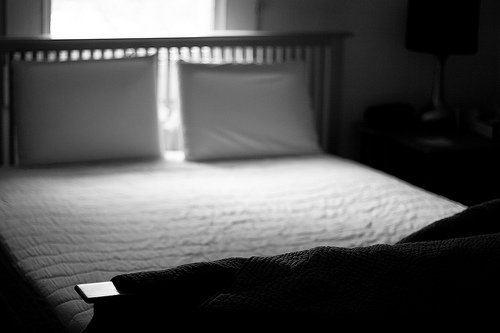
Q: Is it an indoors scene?
A: Yes, it is indoors.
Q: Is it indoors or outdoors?
A: It is indoors.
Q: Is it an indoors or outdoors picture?
A: It is indoors.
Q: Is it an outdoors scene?
A: No, it is indoors.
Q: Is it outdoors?
A: No, it is indoors.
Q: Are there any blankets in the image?
A: Yes, there is a blanket.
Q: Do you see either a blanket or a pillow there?
A: Yes, there is a blanket.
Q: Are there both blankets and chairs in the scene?
A: No, there is a blanket but no chairs.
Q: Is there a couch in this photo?
A: No, there are no couches.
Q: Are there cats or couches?
A: No, there are no couches or cats.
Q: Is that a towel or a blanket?
A: That is a blanket.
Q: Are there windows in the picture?
A: Yes, there is a window.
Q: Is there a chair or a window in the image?
A: Yes, there is a window.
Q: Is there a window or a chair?
A: Yes, there is a window.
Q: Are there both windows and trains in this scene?
A: No, there is a window but no trains.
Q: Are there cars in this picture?
A: No, there are no cars.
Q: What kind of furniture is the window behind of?
A: The window is behind the bed.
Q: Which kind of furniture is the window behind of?
A: The window is behind the bed.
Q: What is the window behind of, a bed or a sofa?
A: The window is behind a bed.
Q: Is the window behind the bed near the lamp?
A: Yes, the window is behind the bed.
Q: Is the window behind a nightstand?
A: No, the window is behind the bed.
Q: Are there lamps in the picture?
A: Yes, there is a lamp.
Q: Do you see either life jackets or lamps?
A: Yes, there is a lamp.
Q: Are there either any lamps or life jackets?
A: Yes, there is a lamp.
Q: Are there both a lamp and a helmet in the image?
A: No, there is a lamp but no helmets.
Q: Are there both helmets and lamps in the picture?
A: No, there is a lamp but no helmets.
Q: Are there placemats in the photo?
A: No, there are no placemats.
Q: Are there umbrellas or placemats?
A: No, there are no placemats or umbrellas.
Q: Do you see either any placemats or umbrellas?
A: No, there are no placemats or umbrellas.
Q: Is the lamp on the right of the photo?
A: Yes, the lamp is on the right of the image.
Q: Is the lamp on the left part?
A: No, the lamp is on the right of the image.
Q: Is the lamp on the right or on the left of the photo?
A: The lamp is on the right of the image.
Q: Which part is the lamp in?
A: The lamp is on the right of the image.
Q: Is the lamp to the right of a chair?
A: No, the lamp is to the right of the pillow.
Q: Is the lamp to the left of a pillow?
A: No, the lamp is to the right of a pillow.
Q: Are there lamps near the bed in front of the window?
A: Yes, there is a lamp near the bed.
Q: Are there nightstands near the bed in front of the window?
A: No, there is a lamp near the bed.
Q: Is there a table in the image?
A: Yes, there is a table.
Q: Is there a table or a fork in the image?
A: Yes, there is a table.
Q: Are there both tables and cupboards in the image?
A: No, there is a table but no cupboards.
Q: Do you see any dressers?
A: No, there are no dressers.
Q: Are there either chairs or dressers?
A: No, there are no dressers or chairs.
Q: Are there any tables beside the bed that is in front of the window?
A: Yes, there is a table beside the bed.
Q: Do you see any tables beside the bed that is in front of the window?
A: Yes, there is a table beside the bed.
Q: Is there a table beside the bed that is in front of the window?
A: Yes, there is a table beside the bed.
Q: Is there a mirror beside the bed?
A: No, there is a table beside the bed.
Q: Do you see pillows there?
A: Yes, there is a pillow.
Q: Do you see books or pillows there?
A: Yes, there is a pillow.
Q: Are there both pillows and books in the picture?
A: No, there is a pillow but no books.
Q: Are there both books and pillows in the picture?
A: No, there is a pillow but no books.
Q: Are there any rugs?
A: No, there are no rugs.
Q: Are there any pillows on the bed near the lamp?
A: Yes, there is a pillow on the bed.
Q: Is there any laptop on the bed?
A: No, there is a pillow on the bed.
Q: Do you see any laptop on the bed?
A: No, there is a pillow on the bed.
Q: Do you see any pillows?
A: Yes, there is a pillow.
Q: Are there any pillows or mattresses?
A: Yes, there is a pillow.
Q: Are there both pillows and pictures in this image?
A: No, there is a pillow but no pictures.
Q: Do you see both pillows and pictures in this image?
A: No, there is a pillow but no pictures.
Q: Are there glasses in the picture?
A: No, there are no glasses.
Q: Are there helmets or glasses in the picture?
A: No, there are no glasses or helmets.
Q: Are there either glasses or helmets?
A: No, there are no glasses or helmets.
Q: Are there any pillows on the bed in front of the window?
A: Yes, there is a pillow on the bed.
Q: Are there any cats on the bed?
A: No, there is a pillow on the bed.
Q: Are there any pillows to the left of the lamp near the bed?
A: Yes, there is a pillow to the left of the lamp.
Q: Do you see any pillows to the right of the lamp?
A: No, the pillow is to the left of the lamp.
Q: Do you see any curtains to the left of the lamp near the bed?
A: No, there is a pillow to the left of the lamp.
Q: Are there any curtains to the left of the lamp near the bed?
A: No, there is a pillow to the left of the lamp.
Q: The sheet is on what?
A: The sheet is on the bed.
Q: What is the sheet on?
A: The sheet is on the bed.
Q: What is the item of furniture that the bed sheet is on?
A: The piece of furniture is a bed.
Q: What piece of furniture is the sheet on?
A: The bed sheet is on the bed.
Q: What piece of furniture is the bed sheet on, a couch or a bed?
A: The bed sheet is on a bed.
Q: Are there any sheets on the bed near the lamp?
A: Yes, there is a sheet on the bed.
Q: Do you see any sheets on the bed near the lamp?
A: Yes, there is a sheet on the bed.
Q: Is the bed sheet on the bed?
A: Yes, the bed sheet is on the bed.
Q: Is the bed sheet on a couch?
A: No, the bed sheet is on the bed.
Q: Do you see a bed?
A: Yes, there is a bed.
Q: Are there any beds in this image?
A: Yes, there is a bed.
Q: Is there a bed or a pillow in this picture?
A: Yes, there is a bed.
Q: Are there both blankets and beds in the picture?
A: Yes, there are both a bed and a blanket.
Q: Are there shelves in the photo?
A: No, there are no shelves.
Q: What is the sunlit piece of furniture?
A: The piece of furniture is a bed.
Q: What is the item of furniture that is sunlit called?
A: The piece of furniture is a bed.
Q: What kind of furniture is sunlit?
A: The furniture is a bed.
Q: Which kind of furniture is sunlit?
A: The furniture is a bed.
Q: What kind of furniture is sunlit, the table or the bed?
A: The bed is sunlit.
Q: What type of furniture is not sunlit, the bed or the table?
A: The table is not sunlit.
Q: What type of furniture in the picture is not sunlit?
A: The furniture is a table.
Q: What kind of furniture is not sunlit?
A: The furniture is a table.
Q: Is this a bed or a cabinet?
A: This is a bed.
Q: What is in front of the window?
A: The bed is in front of the window.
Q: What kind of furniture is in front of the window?
A: The piece of furniture is a bed.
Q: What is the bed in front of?
A: The bed is in front of the window.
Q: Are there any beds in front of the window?
A: Yes, there is a bed in front of the window.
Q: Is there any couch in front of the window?
A: No, there is a bed in front of the window.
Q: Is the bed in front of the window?
A: Yes, the bed is in front of the window.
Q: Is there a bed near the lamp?
A: Yes, there is a bed near the lamp.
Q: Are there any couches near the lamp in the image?
A: No, there is a bed near the lamp.